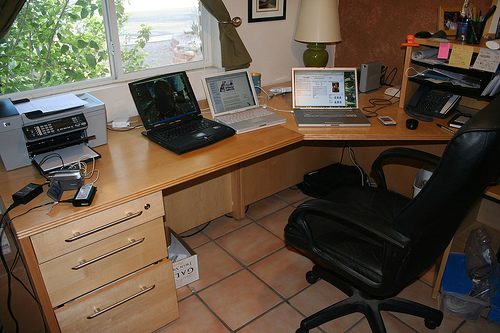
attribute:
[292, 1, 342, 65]
lamp — green, white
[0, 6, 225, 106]
window — glass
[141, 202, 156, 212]
lock — round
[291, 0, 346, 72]
lamp shade — white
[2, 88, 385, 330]
desk — light colored, wooden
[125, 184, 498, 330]
tile flooring — brown, black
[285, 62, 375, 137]
laptop — silver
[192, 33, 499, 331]
chair — black, leather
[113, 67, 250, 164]
laptop — open, black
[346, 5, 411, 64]
wall — dark, brown, sponge, painted, accented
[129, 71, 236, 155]
black laptop — open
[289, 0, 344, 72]
lamp — table top, green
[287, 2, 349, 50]
shade — white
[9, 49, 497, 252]
desk — large, light brown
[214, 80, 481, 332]
chair — black, leather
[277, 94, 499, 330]
chair — black, leather, office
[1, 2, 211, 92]
window — office, metal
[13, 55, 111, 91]
bush — large, green, leafed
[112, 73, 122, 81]
trim — white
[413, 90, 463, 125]
phone — black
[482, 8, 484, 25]
pencil — dark blue